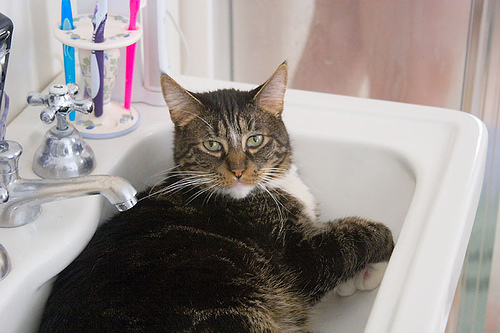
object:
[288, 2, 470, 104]
person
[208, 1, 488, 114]
shower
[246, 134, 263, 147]
eye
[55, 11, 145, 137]
holder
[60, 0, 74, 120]
toothbrushes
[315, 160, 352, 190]
ground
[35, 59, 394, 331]
cat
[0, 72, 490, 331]
sink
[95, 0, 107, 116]
toothbrush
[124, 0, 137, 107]
toothbrush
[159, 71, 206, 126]
ear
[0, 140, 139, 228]
faucet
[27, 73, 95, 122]
handle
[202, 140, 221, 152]
eyes